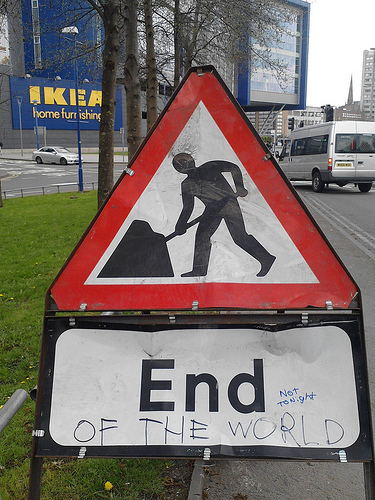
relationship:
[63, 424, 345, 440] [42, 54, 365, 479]
graffiti on a sign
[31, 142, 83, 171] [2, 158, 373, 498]
car in street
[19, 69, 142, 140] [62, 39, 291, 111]
sign on a building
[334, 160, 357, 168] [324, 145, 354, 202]
license plate on a van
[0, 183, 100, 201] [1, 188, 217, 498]
railing next to grass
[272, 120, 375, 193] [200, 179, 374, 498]
car in road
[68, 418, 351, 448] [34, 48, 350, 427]
words that someone wrote on a sign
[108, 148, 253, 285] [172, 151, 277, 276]
image of a man shoveling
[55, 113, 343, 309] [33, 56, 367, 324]
triangular shaped road sign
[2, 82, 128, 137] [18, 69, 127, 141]
big blue and yellow building sign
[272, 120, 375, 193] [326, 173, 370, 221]
car driving on street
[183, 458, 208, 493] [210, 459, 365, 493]
curb between grass and road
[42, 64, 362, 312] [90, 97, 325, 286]
sign has center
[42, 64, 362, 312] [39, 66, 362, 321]
sign has border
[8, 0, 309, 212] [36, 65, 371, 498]
trees behind sign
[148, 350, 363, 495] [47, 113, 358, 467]
cement under sign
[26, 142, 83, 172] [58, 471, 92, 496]
car next to grass